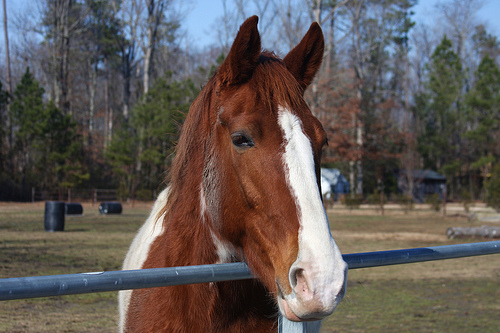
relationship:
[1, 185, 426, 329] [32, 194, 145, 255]
field filled with equipment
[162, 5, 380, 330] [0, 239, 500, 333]
horse leaning over corral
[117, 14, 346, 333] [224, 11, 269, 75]
horse with ear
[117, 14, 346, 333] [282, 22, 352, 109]
horse with ear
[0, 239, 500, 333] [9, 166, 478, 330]
corral in a farm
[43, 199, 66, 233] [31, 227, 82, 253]
barrel in grass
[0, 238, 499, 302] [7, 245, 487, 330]
pole of a fence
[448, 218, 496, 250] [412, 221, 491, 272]
log in grass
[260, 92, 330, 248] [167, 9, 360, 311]
pattern on a horse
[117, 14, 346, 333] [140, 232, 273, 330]
horse near a fence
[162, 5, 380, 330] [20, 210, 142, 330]
horse in a field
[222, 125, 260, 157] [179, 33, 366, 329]
eye on a face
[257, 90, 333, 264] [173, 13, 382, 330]
blaze on horse's head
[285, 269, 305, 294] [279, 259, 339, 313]
nostril on hose's nose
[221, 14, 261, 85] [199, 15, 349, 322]
ear are on head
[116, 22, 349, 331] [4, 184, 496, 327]
building near corral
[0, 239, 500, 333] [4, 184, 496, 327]
corral on far of corral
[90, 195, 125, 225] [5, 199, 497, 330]
barrel in a field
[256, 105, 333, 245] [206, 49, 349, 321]
blaze on face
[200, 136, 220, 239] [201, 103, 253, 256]
dirt on cheek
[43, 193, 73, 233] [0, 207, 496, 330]
barrel in a path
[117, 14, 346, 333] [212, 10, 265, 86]
horse has ear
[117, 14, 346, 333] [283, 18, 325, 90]
horse has ear